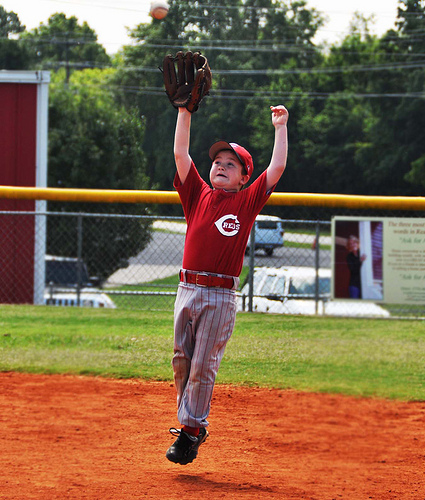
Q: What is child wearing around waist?
A: A belt.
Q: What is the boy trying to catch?
A: A baseball.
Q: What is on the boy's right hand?
A: A catcher's mitt.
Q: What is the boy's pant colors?
A: Gray with burgundy stripes.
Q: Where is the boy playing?
A: Baseball field.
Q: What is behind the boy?
A: A yellow pole.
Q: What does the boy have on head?
A: A baseball cap.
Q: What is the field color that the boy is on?
A: Reddish.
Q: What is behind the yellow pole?
A: A chain link fence.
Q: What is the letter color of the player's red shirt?
A: White.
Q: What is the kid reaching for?
A: A ball.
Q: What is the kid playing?
A: Baseball.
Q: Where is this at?
A: A baseball field.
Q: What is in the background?
A: A yellow and gray metal fence.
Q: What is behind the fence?
A: Cars.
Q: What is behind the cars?
A: Green trees.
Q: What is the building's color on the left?
A: Red.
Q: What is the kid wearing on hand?
A: Glove.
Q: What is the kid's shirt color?
A: Red.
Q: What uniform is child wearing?
A: A uniform for the Chicago Reds.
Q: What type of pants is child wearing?
A: Dark gray pants with red pinstripes.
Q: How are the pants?
A: Gray with red stripes.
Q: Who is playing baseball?
A: A boy.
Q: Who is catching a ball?
A: A boy.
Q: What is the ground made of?
A: Dirt and grass.